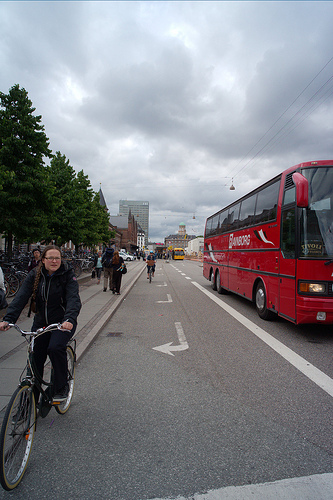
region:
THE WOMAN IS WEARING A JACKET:
[4, 264, 84, 349]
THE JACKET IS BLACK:
[10, 264, 88, 333]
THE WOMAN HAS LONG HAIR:
[24, 242, 72, 317]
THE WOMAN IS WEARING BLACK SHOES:
[21, 383, 71, 415]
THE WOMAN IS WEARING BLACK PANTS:
[20, 317, 82, 410]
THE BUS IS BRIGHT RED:
[197, 156, 332, 337]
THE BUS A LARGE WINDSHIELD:
[277, 164, 332, 272]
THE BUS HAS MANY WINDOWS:
[193, 172, 280, 240]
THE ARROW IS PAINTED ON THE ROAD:
[145, 314, 195, 361]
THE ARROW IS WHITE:
[152, 315, 196, 365]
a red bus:
[190, 155, 328, 329]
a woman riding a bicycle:
[1, 246, 79, 490]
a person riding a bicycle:
[143, 248, 155, 282]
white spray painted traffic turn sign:
[152, 320, 186, 358]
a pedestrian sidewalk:
[0, 250, 151, 439]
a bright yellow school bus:
[166, 245, 184, 260]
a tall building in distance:
[117, 199, 150, 247]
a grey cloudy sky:
[0, 2, 331, 243]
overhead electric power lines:
[157, 62, 330, 231]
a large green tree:
[1, 76, 57, 242]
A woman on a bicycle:
[1, 244, 86, 484]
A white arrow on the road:
[147, 312, 196, 366]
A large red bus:
[200, 157, 331, 360]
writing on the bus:
[217, 230, 260, 247]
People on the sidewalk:
[91, 235, 131, 301]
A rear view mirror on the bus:
[283, 167, 314, 214]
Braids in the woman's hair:
[22, 252, 54, 319]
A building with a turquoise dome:
[160, 217, 205, 255]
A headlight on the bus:
[292, 272, 326, 300]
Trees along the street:
[0, 78, 114, 270]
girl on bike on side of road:
[0, 243, 103, 488]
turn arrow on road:
[154, 314, 198, 376]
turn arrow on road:
[151, 284, 176, 307]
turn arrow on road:
[157, 279, 169, 289]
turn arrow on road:
[154, 269, 166, 275]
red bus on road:
[197, 175, 326, 339]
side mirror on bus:
[288, 177, 305, 209]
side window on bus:
[283, 184, 302, 257]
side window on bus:
[256, 186, 280, 224]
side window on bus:
[240, 199, 255, 223]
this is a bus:
[210, 172, 326, 298]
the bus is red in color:
[250, 243, 272, 264]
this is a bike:
[0, 379, 27, 446]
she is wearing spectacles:
[44, 253, 60, 263]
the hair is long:
[32, 267, 42, 285]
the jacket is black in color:
[51, 277, 68, 306]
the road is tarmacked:
[173, 360, 239, 434]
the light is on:
[303, 283, 324, 294]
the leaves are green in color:
[18, 156, 58, 204]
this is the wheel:
[246, 287, 261, 307]